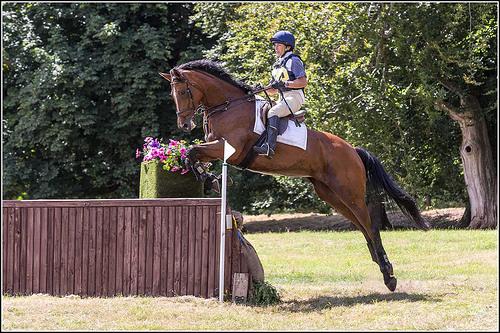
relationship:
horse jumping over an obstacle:
[148, 46, 440, 294] [3, 187, 275, 307]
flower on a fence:
[167, 162, 181, 173] [0, 192, 229, 299]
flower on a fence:
[177, 161, 189, 176] [0, 192, 229, 299]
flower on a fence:
[132, 145, 142, 156] [0, 192, 229, 299]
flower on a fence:
[143, 132, 155, 144] [0, 192, 229, 299]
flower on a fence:
[202, 159, 214, 169] [0, 192, 229, 299]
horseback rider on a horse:
[251, 28, 306, 160] [158, 60, 428, 291]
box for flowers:
[128, 155, 208, 197] [133, 127, 225, 173]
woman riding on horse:
[233, 15, 378, 213] [159, 66, 414, 230]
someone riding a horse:
[217, 28, 352, 202] [95, 29, 460, 315]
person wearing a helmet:
[250, 29, 307, 158] [269, 29, 296, 49]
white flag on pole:
[224, 141, 234, 160] [218, 164, 230, 304]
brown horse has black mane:
[159, 61, 428, 291] [172, 60, 251, 92]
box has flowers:
[128, 155, 208, 197] [128, 126, 198, 178]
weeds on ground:
[251, 277, 288, 312] [4, 188, 496, 325]